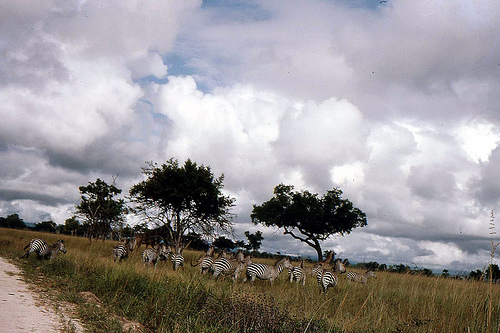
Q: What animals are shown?
A: Zebras.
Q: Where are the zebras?
A: In the wild.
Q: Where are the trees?
A: Behind the zebras.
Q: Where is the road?
A: On the left.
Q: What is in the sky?
A: Clouds.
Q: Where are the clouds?
A: In the sky.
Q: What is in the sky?
A: The sky is full of clouds.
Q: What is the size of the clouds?
A: The clouds are big.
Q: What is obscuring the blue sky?
A: The white clouds.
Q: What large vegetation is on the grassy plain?
A: A few trees.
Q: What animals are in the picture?
A: Zebras.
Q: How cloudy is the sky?
A: There are thick white clouds in the sky.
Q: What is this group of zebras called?
A: A herd of zebras.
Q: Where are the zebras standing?
A: On the grass.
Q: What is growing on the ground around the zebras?
A: Tall grass.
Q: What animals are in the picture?
A: A herd of zebras.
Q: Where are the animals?
A: In tall grass.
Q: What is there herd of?
A: Zebras.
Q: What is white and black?
A: Zebra.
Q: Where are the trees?
A: Near the zebras.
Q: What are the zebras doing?
A: Walking.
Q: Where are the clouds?
A: In the sky.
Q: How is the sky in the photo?
A: Cloudy.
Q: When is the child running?
A: Is no child.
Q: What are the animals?
A: Zebras.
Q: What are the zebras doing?
A: Running.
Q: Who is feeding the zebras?
A: No one.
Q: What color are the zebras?
A: Black and white.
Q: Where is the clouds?
A: In the sky.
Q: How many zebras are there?
A: 12.